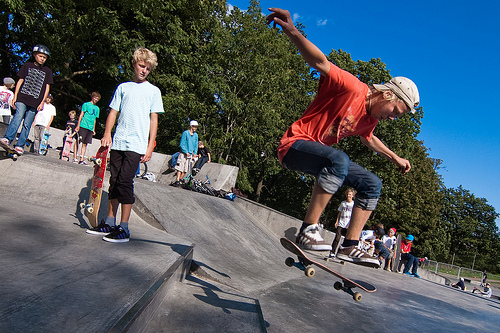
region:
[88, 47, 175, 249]
The boy is holding a skateboard in his hand.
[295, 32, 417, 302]
The person is doing a trick on the skateboard.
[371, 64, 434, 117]
The boy has a cap on his head.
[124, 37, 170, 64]
The boy has blonde hair.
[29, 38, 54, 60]
The boy is wearing a helmet.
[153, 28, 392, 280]
The boy is skateboarding on a ramp.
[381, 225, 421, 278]
People are sitting at the skateboard park.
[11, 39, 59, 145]
The person is standing on the skateboard.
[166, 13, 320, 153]
The trees are green.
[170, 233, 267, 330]
A shadow on the steps.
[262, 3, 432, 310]
This man in on a skateboard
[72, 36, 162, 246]
This boy is holding a skateboard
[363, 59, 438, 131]
this man is wearing a baseball cap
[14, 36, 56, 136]
this person is wearing a black shirt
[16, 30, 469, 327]
these people are at a skate park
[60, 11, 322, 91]
there are trees in the backgournd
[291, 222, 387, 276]
the mans feet are not touching the skateboard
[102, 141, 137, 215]
the boys is wearing black shorts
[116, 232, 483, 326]
the skate part is made up of concrete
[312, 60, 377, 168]
the man is wearing an orange shirt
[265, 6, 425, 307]
Young boy skateboarding on a skateboard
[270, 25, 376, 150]
Skateboarder wearing a red tee shirt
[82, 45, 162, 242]
Young boy watching the skateboarder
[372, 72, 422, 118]
Beige cap worn by skateboarder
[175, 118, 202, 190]
Young boy in the distance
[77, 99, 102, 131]
Green tee shirt worn by young boy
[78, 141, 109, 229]
Skateboard held by young boy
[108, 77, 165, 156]
White tee shirt worn by young boy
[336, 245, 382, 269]
Red and white tennis shoe on boy's left foot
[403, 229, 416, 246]
Man wearing a blue cap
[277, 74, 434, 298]
boy in red shirt doing trick on skateboard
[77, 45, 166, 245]
boy in blue shirt watching skater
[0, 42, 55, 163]
young girl wearing helmet standing on skateboard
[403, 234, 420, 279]
boy in blue hat and shoes watching skaters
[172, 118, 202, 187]
boy in white helmet getting ready to skate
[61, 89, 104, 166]
boy in green shirt holding red skateboard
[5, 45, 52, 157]
girl in red shoes waiting to skate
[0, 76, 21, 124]
boy in grey hat talking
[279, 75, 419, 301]
boy doing trick in the air off board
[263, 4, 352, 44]
clear sky with a few clouds over skate park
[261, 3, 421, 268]
a boy in mid air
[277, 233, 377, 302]
a skateboard in mid air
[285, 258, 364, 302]
the wheels on the skate board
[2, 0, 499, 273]
the tall green trees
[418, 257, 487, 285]
the metal barricades in the background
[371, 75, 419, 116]
the hat on the boy's head in mid air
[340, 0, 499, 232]
a part of the clear blue sky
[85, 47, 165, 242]
the boy standing with his skateboard in front of him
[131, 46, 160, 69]
the blond hair on the boy's head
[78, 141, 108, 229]
the skateboard in front of the boy